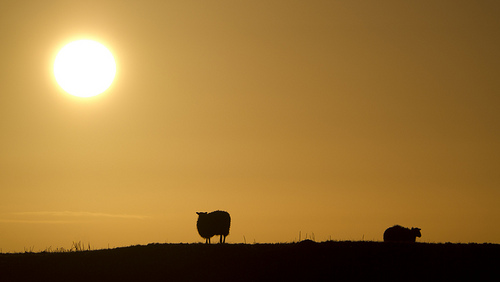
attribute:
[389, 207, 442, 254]
sheep down — lying down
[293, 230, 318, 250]
pile — small 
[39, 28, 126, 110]
ground — black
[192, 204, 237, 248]
sheep — standing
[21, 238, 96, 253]
blades — tall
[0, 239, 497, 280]
ground — black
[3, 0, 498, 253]
sky — yellow, clear, cloudless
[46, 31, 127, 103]
sun — rising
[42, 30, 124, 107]
sun — shining, rising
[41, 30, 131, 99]
sun — circle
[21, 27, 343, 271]
picture — outdoors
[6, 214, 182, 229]
clouds — thin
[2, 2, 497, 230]
sky — orange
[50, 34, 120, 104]
sun — bright, round